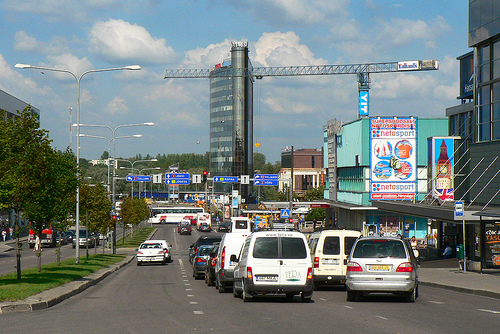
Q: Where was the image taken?
A: It was taken at the street.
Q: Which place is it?
A: It is a street.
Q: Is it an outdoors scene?
A: Yes, it is outdoors.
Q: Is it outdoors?
A: Yes, it is outdoors.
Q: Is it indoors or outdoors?
A: It is outdoors.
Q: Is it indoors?
A: No, it is outdoors.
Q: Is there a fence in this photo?
A: No, there are no fences.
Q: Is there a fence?
A: No, there are no fences.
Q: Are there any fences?
A: No, there are no fences.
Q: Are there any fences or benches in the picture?
A: No, there are no fences or benches.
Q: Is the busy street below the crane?
A: Yes, the street is below the crane.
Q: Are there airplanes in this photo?
A: No, there are no airplanes.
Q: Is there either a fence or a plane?
A: No, there are no airplanes or fences.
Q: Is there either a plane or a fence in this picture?
A: No, there are no airplanes or fences.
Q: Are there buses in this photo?
A: Yes, there is a bus.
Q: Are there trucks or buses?
A: Yes, there is a bus.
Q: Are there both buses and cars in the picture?
A: Yes, there are both a bus and a car.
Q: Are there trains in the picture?
A: No, there are no trains.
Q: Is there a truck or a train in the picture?
A: No, there are no trains or trucks.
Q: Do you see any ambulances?
A: No, there are no ambulances.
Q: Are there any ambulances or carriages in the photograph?
A: No, there are no ambulances or carriages.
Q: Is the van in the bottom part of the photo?
A: Yes, the van is in the bottom of the image.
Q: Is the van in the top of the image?
A: No, the van is in the bottom of the image.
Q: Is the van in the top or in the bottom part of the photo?
A: The van is in the bottom of the image.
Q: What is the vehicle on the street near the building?
A: The vehicle is a van.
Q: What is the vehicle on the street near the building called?
A: The vehicle is a van.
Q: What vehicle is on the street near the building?
A: The vehicle is a van.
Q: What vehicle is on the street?
A: The vehicle is a van.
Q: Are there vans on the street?
A: Yes, there is a van on the street.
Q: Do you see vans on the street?
A: Yes, there is a van on the street.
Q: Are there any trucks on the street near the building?
A: No, there is a van on the street.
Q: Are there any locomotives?
A: No, there are no locomotives.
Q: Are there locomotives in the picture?
A: No, there are no locomotives.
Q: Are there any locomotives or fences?
A: No, there are no locomotives or fences.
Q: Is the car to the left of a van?
A: Yes, the car is to the left of a van.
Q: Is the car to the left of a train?
A: No, the car is to the left of a van.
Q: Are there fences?
A: No, there are no fences.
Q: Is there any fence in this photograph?
A: No, there are no fences.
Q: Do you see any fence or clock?
A: No, there are no fences or clocks.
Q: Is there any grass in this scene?
A: Yes, there is grass.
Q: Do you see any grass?
A: Yes, there is grass.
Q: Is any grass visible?
A: Yes, there is grass.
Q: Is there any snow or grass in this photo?
A: Yes, there is grass.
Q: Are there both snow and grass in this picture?
A: No, there is grass but no snow.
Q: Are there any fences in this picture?
A: No, there are no fences.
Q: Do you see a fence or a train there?
A: No, there are no fences or trains.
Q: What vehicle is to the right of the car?
A: The vehicle is a van.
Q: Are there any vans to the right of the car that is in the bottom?
A: Yes, there is a van to the right of the car.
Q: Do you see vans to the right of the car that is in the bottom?
A: Yes, there is a van to the right of the car.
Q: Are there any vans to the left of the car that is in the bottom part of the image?
A: No, the van is to the right of the car.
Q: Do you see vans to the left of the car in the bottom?
A: No, the van is to the right of the car.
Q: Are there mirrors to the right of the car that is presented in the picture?
A: No, there is a van to the right of the car.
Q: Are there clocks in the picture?
A: No, there are no clocks.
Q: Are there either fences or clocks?
A: No, there are no clocks or fences.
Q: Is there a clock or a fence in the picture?
A: No, there are no clocks or fences.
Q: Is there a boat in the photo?
A: No, there are no boats.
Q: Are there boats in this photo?
A: No, there are no boats.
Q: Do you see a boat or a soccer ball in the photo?
A: No, there are no boats or soccer balls.